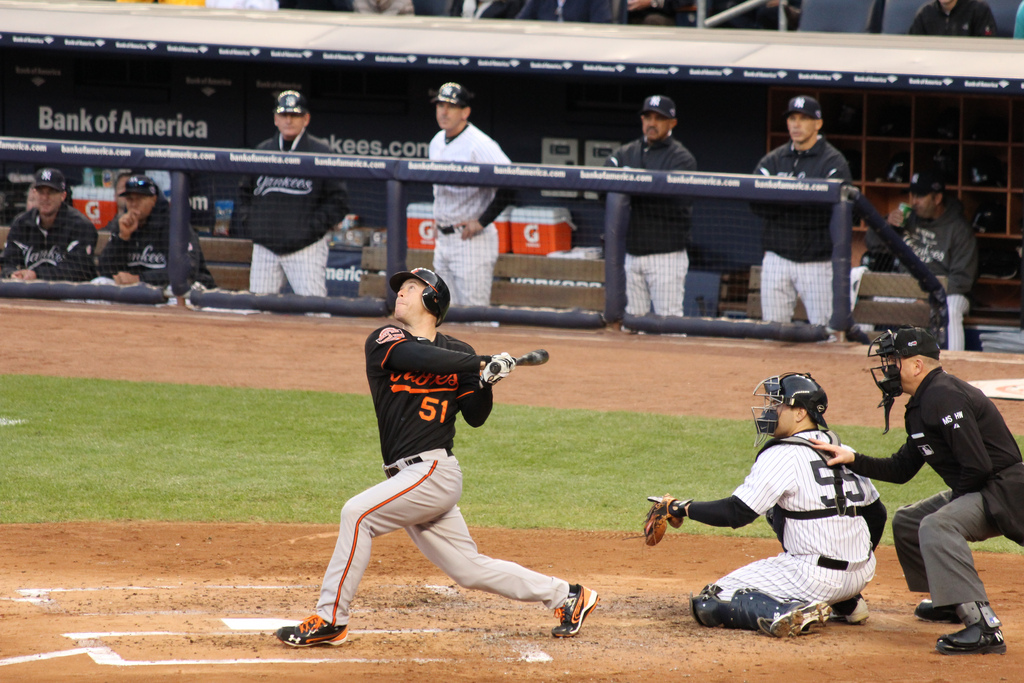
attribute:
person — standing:
[241, 81, 350, 291]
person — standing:
[411, 89, 522, 303]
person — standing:
[612, 93, 705, 314]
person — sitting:
[77, 165, 207, 287]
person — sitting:
[14, 160, 97, 281]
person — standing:
[409, 67, 531, 301]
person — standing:
[602, 83, 713, 319]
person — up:
[743, 83, 847, 328]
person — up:
[758, 98, 843, 325]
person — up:
[754, 94, 850, 324]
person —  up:
[758, 91, 847, 336]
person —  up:
[751, 87, 855, 317]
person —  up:
[751, 87, 844, 325]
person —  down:
[84, 173, 210, 288]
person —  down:
[88, 176, 214, 280]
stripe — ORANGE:
[325, 454, 440, 623]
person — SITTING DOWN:
[3, 154, 99, 278]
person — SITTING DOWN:
[93, 173, 189, 282]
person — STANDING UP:
[229, 83, 361, 293]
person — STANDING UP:
[420, 78, 524, 303]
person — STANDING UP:
[606, 89, 697, 321]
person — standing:
[752, 91, 852, 340]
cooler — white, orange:
[506, 201, 578, 253]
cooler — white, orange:
[490, 201, 517, 253]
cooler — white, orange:
[402, 197, 441, 250]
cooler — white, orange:
[65, 178, 124, 230]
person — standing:
[599, 89, 697, 338]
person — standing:
[423, 80, 516, 329]